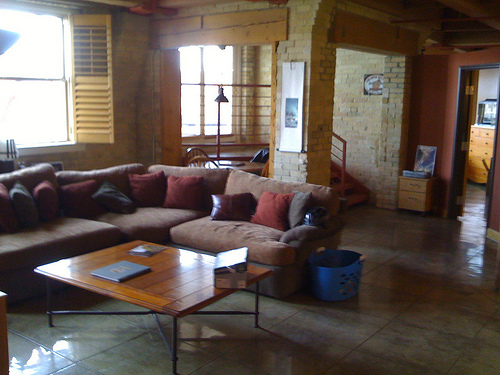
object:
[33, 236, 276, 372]
table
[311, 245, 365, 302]
pail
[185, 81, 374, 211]
starcase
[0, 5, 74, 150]
window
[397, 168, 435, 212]
dresser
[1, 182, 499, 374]
floor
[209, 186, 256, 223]
pillow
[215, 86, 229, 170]
lamp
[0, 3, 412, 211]
wall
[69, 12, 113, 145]
shudder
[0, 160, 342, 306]
couch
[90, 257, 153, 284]
book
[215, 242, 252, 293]
box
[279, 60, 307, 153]
calender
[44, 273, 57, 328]
leg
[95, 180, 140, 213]
pillow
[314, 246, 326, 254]
handle